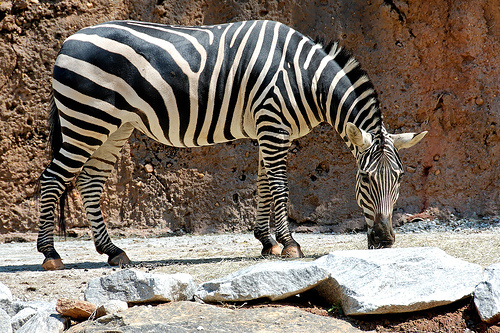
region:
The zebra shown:
[15, 13, 428, 271]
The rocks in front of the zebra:
[2, 244, 499, 331]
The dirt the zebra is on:
[2, 219, 499, 261]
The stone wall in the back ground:
[0, 0, 495, 232]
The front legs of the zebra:
[245, 116, 309, 258]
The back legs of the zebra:
[32, 111, 141, 269]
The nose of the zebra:
[365, 218, 400, 248]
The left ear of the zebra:
[341, 120, 374, 151]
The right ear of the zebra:
[390, 127, 430, 152]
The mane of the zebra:
[316, 36, 390, 142]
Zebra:
[23, 31, 426, 276]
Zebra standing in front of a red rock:
[10, 20, 488, 284]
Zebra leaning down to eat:
[306, 29, 475, 256]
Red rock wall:
[425, 21, 482, 243]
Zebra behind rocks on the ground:
[24, 41, 451, 328]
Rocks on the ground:
[275, 221, 474, 318]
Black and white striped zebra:
[21, 21, 461, 261]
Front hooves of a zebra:
[251, 217, 306, 277]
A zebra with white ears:
[342, 113, 434, 253]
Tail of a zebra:
[48, 91, 63, 170]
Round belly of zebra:
[132, 93, 252, 149]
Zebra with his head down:
[327, 121, 434, 248]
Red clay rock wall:
[393, 9, 488, 114]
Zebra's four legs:
[29, 155, 319, 267]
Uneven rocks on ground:
[90, 273, 386, 325]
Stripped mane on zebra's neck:
[312, 33, 408, 133]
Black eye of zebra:
[354, 168, 375, 188]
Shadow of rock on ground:
[356, 313, 405, 325]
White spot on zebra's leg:
[100, 138, 128, 155]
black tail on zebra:
[43, 98, 63, 156]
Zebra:
[44, 15, 495, 220]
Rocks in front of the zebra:
[101, 181, 339, 306]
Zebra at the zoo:
[13, 54, 438, 229]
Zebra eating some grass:
[330, 82, 432, 251]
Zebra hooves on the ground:
[39, 213, 149, 285]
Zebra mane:
[300, 41, 438, 172]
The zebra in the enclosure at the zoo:
[16, 20, 358, 272]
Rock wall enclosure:
[120, 2, 473, 192]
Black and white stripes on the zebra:
[52, 10, 446, 185]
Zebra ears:
[321, 100, 436, 165]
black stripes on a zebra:
[128, 69, 200, 101]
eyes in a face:
[356, 171, 418, 186]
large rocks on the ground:
[229, 264, 420, 314]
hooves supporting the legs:
[254, 237, 314, 259]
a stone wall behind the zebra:
[428, 34, 480, 177]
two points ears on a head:
[347, 114, 437, 148]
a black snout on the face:
[366, 214, 414, 258]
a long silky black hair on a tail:
[51, 99, 57, 154]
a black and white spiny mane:
[354, 54, 391, 131]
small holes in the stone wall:
[425, 96, 452, 194]